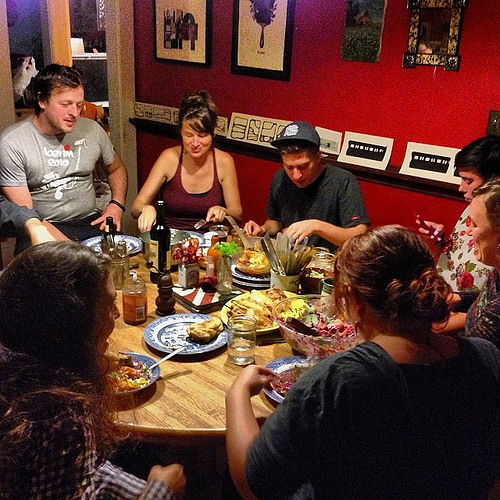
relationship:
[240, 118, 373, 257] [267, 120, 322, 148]
man wearing hat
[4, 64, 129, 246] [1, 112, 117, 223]
man wearing tshirt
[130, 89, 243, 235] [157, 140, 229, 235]
woman in top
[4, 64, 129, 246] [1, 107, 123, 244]
man wearing t shirt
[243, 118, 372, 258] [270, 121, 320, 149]
man wearing ball cap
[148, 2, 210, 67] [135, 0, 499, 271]
frames on wall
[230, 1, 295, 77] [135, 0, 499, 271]
frames on wall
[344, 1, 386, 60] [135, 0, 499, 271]
frames on wall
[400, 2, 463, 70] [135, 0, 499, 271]
frames on wall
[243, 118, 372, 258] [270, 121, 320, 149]
man wears ball cap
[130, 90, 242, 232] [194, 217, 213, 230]
woman with fork